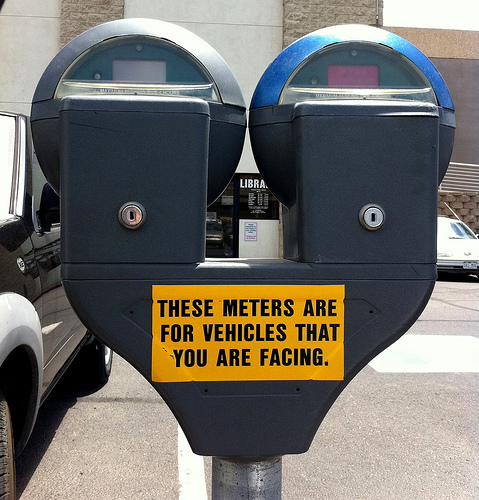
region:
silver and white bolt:
[363, 196, 386, 241]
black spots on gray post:
[211, 466, 279, 490]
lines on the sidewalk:
[107, 388, 143, 407]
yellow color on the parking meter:
[132, 275, 374, 398]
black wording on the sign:
[163, 297, 331, 367]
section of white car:
[441, 204, 469, 272]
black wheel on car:
[3, 438, 34, 494]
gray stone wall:
[59, 5, 111, 15]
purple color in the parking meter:
[327, 57, 385, 92]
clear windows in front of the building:
[209, 210, 243, 244]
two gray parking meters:
[48, 12, 459, 455]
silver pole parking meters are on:
[210, 457, 282, 498]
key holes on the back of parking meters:
[108, 195, 386, 229]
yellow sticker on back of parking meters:
[152, 282, 343, 380]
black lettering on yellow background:
[154, 289, 341, 371]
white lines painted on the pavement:
[170, 421, 223, 497]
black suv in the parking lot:
[2, 100, 132, 412]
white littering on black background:
[236, 175, 276, 212]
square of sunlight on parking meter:
[195, 249, 249, 270]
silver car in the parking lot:
[436, 214, 477, 272]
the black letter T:
[154, 295, 171, 317]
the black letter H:
[165, 294, 184, 322]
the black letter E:
[177, 295, 194, 321]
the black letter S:
[187, 296, 205, 318]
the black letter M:
[219, 295, 239, 320]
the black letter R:
[267, 295, 286, 320]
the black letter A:
[299, 294, 317, 319]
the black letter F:
[161, 318, 172, 344]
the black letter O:
[165, 320, 184, 347]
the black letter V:
[201, 315, 215, 345]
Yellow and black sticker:
[144, 280, 346, 381]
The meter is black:
[37, 23, 448, 467]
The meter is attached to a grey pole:
[215, 456, 294, 497]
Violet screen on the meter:
[325, 60, 385, 94]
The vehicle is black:
[5, 99, 123, 487]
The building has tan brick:
[1, 1, 385, 120]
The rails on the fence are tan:
[438, 155, 475, 188]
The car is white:
[436, 205, 476, 270]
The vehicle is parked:
[0, 105, 108, 488]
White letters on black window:
[237, 173, 274, 194]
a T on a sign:
[156, 297, 169, 321]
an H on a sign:
[166, 297, 179, 315]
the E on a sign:
[179, 297, 191, 314]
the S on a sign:
[191, 297, 201, 318]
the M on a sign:
[220, 296, 239, 315]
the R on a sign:
[270, 298, 283, 316]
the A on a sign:
[301, 296, 314, 315]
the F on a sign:
[159, 322, 171, 345]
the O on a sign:
[167, 323, 183, 343]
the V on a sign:
[200, 320, 213, 341]